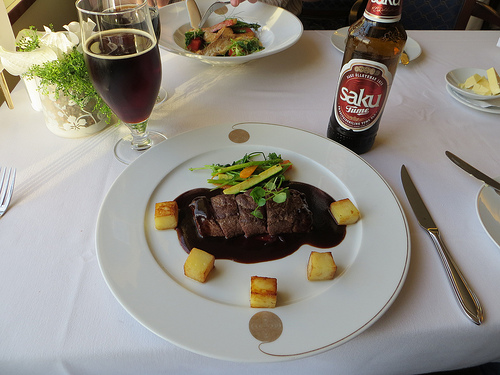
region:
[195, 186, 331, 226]
piece of steak on plate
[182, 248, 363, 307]
little square pineapples cut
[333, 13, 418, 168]
saku beer bottle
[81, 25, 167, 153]
glass wine glass full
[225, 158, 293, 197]
a small section of garnish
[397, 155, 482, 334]
silver knife on table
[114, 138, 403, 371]
white and gold dinner plate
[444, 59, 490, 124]
small plate of butter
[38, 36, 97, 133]
vase with green plant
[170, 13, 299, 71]
bowl of chicken salad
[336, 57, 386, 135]
a brand name of a liqour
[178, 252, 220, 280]
a piece of meat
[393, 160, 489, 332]
a small knief to cut meat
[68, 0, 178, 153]
a wine glass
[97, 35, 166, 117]
drink in the glass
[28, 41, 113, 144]
greenish plant beside the bottle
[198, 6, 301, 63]
a white plate with food items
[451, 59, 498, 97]
a white plate having snacks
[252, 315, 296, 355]
a small piece of art on the plate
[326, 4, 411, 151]
a big bottle to drink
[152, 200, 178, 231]
a tiny cubed potato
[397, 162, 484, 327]
silver butter knife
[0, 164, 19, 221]
partial head of a fork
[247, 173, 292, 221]
a few sprigs of parsely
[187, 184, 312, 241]
small welldone steak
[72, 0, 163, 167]
medium sized glass full of dark beer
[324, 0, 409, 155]
brown glass bottle of beer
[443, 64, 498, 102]
tiny white dish of butter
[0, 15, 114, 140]
white frilly table decoration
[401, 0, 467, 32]
blue and yellow fabric pattern on the chair back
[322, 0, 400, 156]
beer on the table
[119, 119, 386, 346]
a plate of steak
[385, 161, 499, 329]
a silver butterknife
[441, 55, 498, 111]
a dish filled with butter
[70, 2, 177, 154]
a glass with a beverage in it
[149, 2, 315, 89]
a white bowl of food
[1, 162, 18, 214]
the prongs of a fork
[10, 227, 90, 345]
pure white tablecloth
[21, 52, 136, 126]
greens on a table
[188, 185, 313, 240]
steak with sauce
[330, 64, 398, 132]
Saku lable on bottle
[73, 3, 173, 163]
Full clear wine glass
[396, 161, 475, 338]
Long silver steak knife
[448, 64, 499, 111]
Small bowl of yellow butter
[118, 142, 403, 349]
Large plate of gourmet food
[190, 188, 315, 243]
Large cut steak with sauce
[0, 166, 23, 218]
Small silver dining fork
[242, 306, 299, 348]
Small circular brown design on plate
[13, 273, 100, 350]
Long white table cloth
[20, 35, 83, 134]
Greenery on a decor item